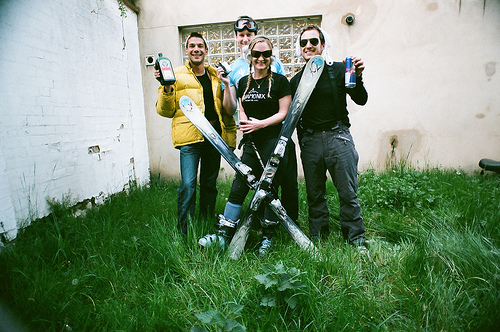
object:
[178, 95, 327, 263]
skis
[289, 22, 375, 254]
person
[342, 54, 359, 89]
red bull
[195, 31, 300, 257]
person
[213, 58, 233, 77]
bottle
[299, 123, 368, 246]
pants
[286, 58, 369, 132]
shirt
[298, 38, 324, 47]
sunglasses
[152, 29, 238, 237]
man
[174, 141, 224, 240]
jeans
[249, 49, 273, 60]
sunglasses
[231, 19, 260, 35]
goggles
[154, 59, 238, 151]
jacket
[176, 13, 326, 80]
window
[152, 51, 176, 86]
bottle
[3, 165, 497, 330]
area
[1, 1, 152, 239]
wall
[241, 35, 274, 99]
hair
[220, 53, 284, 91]
shirt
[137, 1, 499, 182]
wall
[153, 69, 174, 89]
hand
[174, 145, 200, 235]
leg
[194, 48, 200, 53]
nose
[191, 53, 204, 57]
mouth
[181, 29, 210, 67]
head